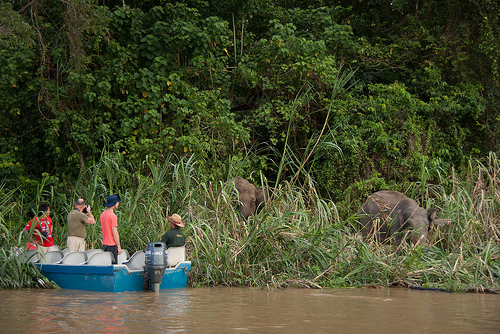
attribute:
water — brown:
[24, 292, 415, 333]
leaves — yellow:
[131, 81, 169, 126]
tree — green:
[79, 23, 295, 187]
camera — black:
[41, 227, 51, 243]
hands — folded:
[22, 239, 44, 252]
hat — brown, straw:
[168, 216, 187, 230]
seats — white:
[49, 245, 118, 264]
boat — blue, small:
[25, 262, 193, 291]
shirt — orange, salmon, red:
[99, 212, 113, 245]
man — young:
[94, 188, 130, 262]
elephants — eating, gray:
[200, 180, 442, 244]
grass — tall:
[196, 219, 466, 279]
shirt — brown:
[67, 211, 86, 236]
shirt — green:
[164, 232, 188, 250]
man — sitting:
[156, 211, 188, 253]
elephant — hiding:
[348, 186, 453, 275]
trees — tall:
[32, 34, 278, 185]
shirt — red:
[26, 216, 59, 247]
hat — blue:
[101, 195, 124, 207]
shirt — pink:
[102, 208, 120, 244]